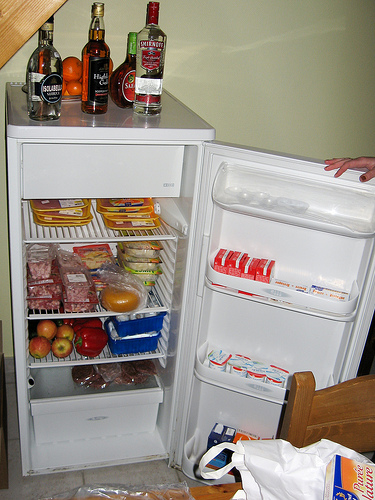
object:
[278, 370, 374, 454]
chair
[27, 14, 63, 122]
bottle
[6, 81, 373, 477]
fridge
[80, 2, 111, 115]
bottle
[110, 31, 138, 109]
bottle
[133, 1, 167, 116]
bottle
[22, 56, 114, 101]
oranges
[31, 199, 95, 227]
meat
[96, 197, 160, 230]
meat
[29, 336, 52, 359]
apple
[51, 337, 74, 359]
apple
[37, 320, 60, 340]
apple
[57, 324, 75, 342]
apple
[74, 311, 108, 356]
red pepper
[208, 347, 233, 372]
yogurt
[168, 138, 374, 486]
door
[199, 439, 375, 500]
bag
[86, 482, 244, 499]
table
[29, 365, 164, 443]
drawer